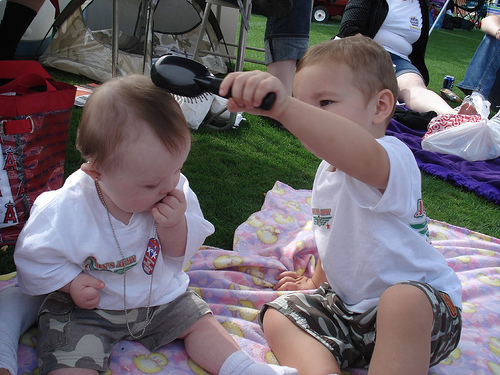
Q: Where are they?
A: On the ground.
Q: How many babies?
A: 2.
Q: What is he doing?
A: Playing.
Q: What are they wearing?
A: Shorts.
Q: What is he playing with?
A: Brush.